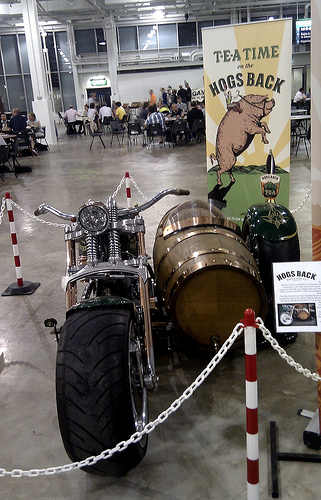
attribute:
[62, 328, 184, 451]
tire — thick, fat, wide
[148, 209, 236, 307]
barrel — brown, wooden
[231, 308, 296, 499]
pole — thin, striped, red, white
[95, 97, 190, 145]
people — sitting, standing, seated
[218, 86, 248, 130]
man — riding, wearing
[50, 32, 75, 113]
windows — tall, shiny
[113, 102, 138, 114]
shirt — yellow, blue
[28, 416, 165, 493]
chains — white, plastic, linked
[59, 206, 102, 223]
headlight — round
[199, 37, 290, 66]
letters — green, black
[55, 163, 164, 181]
floor — gray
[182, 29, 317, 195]
sign — yellow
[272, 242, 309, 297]
sign — white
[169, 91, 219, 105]
shirt — black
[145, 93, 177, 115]
shirt — orange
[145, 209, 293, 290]
sidecar — shaped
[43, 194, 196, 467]
motorcycle — displayed, chromed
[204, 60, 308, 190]
advertisement — displayed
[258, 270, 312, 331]
information — displayed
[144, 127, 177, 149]
chair — black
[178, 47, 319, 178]
banner — large